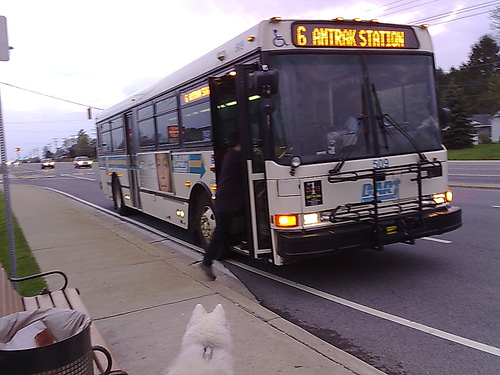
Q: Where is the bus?
A: On the street.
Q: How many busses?
A: One.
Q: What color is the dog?
A: White.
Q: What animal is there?
A: Dog.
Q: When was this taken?
A: During the day.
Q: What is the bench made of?
A: Wood.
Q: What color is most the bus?
A: White.